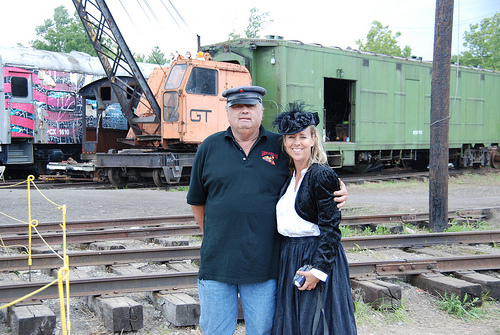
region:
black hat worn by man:
[208, 66, 268, 110]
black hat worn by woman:
[277, 102, 327, 136]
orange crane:
[135, 48, 215, 139]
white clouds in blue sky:
[138, 16, 153, 41]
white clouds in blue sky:
[197, 12, 219, 37]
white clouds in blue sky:
[298, 18, 328, 46]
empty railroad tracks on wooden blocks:
[7, 222, 196, 296]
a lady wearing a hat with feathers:
[272, 98, 334, 168]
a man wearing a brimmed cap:
[215, 72, 265, 142]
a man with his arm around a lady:
[184, 80, 369, 333]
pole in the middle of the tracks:
[426, 14, 456, 239]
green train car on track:
[230, 30, 498, 148]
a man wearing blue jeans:
[192, 274, 275, 334]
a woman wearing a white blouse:
[265, 163, 343, 243]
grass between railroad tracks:
[355, 210, 492, 240]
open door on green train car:
[317, 65, 375, 149]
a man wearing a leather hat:
[218, 85, 268, 112]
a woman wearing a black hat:
[278, 105, 319, 140]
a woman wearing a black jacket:
[277, 160, 349, 252]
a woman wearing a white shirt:
[274, 164, 314, 241]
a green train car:
[288, 56, 495, 176]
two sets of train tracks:
[0, 206, 159, 321]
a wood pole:
[419, 2, 473, 226]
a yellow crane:
[80, 0, 250, 187]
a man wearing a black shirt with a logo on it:
[180, 123, 278, 298]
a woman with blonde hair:
[303, 111, 332, 175]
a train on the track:
[291, 24, 489, 299]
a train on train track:
[247, 15, 439, 203]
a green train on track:
[254, 33, 489, 229]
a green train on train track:
[261, 38, 382, 140]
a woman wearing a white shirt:
[278, 90, 400, 328]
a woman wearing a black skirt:
[274, 138, 383, 297]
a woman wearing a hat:
[272, 111, 317, 164]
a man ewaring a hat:
[205, 79, 270, 169]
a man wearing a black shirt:
[219, 90, 300, 284]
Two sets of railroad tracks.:
[75, 197, 204, 322]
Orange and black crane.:
[52, 0, 262, 180]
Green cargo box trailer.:
[248, 15, 498, 180]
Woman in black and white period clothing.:
[270, 87, 361, 334]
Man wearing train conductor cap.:
[156, 60, 295, 191]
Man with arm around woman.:
[181, 56, 366, 330]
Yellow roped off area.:
[0, 155, 85, 332]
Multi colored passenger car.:
[6, 38, 181, 183]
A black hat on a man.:
[220, 84, 266, 108]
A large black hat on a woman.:
[270, 102, 319, 136]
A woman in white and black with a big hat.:
[276, 101, 358, 333]